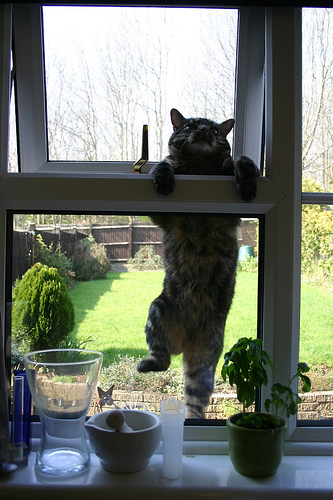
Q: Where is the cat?
A: In the window.